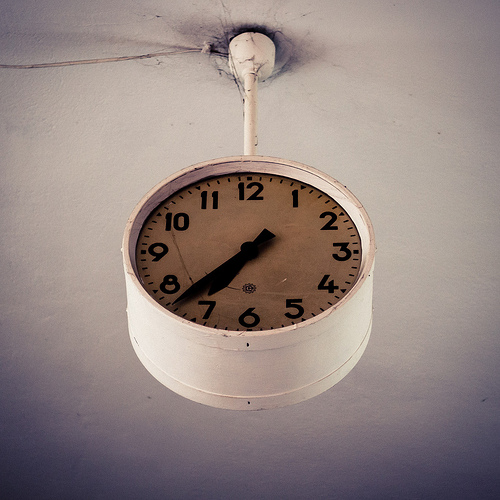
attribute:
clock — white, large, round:
[120, 155, 377, 412]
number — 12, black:
[236, 180, 265, 202]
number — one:
[290, 188, 302, 209]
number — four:
[317, 273, 340, 296]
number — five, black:
[282, 297, 307, 320]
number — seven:
[197, 299, 218, 321]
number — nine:
[147, 240, 170, 263]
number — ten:
[163, 210, 192, 231]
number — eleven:
[198, 188, 220, 211]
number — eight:
[158, 274, 181, 295]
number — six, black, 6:
[237, 306, 261, 328]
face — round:
[136, 172, 363, 331]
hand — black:
[172, 228, 277, 303]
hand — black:
[208, 240, 252, 295]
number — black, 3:
[332, 242, 353, 263]